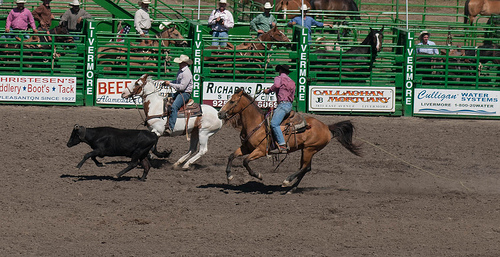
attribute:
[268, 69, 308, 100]
shirt — red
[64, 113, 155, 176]
cow — small, black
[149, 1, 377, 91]
fence — tall, green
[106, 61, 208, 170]
horse — white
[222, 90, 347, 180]
horse — brown, running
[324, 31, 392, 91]
horse — black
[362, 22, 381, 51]
stripe — white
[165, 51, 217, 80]
hat — white, cowboy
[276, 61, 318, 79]
hat — cowboy, black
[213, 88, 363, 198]
horse — brown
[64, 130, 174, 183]
animal — black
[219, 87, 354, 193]
horse — brown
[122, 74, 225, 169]
horse — white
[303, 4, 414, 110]
gate — green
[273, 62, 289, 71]
hat — black